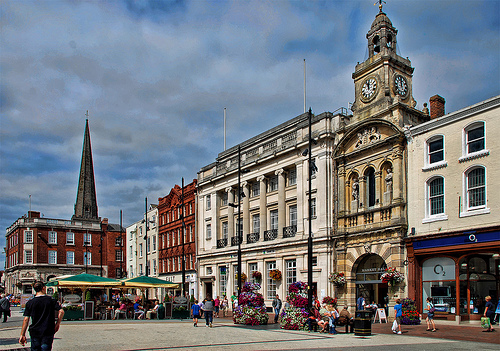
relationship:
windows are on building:
[218, 196, 303, 246] [198, 109, 351, 310]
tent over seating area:
[120, 270, 182, 289] [55, 290, 182, 319]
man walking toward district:
[16, 280, 64, 351] [19, 107, 487, 343]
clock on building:
[359, 76, 377, 99] [329, 0, 429, 321]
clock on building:
[392, 75, 409, 96] [326, 20, 433, 319]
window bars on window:
[215, 227, 310, 249] [266, 207, 276, 232]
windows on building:
[42, 229, 95, 262] [7, 218, 125, 265]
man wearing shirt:
[16, 280, 64, 351] [23, 294, 63, 335]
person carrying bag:
[383, 292, 412, 337] [388, 317, 400, 334]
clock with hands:
[359, 76, 377, 99] [365, 78, 371, 89]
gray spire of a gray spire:
[66, 101, 108, 241] [70, 109, 101, 222]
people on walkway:
[190, 298, 202, 326] [1, 301, 498, 349]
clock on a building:
[355, 72, 385, 104] [329, 0, 429, 321]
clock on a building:
[390, 73, 410, 98] [329, 0, 429, 321]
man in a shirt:
[22, 274, 62, 311] [31, 295, 55, 330]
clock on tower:
[359, 76, 377, 99] [351, 0, 413, 110]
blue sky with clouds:
[0, 2, 499, 232] [127, 0, 294, 105]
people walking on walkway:
[176, 273, 236, 325] [408, 319, 497, 330]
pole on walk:
[233, 145, 241, 307] [201, 305, 352, 315]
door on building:
[349, 254, 389, 321] [330, 0, 445, 325]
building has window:
[158, 177, 195, 298] [187, 225, 193, 242]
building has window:
[158, 177, 195, 298] [160, 233, 165, 249]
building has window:
[158, 177, 195, 298] [166, 232, 170, 247]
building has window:
[158, 177, 195, 298] [169, 230, 175, 245]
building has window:
[158, 177, 195, 298] [177, 228, 182, 244]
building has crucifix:
[4, 105, 132, 298] [81, 102, 91, 119]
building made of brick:
[403, 110, 493, 320] [34, 231, 100, 266]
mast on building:
[217, 102, 233, 149] [198, 109, 351, 310]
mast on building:
[298, 55, 311, 109] [198, 109, 351, 310]